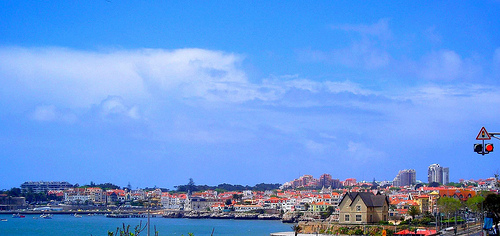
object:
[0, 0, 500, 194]
sky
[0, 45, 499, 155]
clouds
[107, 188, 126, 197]
roof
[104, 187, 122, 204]
building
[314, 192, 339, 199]
roof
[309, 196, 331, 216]
building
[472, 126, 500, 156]
traffic sign